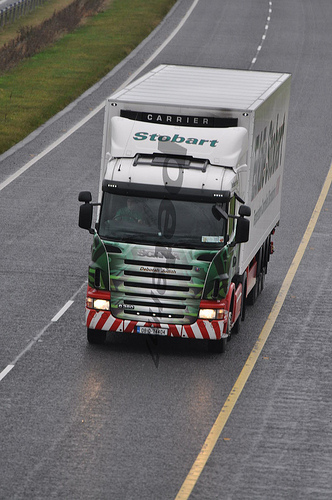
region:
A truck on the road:
[35, 52, 310, 449]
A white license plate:
[131, 317, 171, 339]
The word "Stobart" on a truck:
[129, 126, 222, 153]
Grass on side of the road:
[0, 12, 166, 170]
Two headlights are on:
[90, 293, 219, 325]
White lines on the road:
[1, 2, 275, 382]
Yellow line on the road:
[171, 160, 329, 498]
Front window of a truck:
[95, 184, 232, 249]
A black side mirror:
[72, 187, 102, 238]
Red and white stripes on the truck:
[83, 301, 229, 343]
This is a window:
[115, 188, 300, 302]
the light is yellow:
[77, 296, 248, 317]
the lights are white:
[87, 283, 294, 309]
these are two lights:
[89, 284, 271, 348]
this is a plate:
[107, 316, 171, 356]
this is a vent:
[138, 242, 172, 320]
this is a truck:
[94, 255, 256, 356]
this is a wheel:
[214, 292, 250, 368]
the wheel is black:
[192, 292, 266, 392]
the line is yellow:
[183, 442, 227, 488]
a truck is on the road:
[70, 74, 305, 301]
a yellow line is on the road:
[143, 405, 265, 498]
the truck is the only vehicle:
[83, 126, 306, 347]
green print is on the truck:
[121, 119, 281, 187]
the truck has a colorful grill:
[91, 244, 328, 386]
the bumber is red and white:
[86, 284, 303, 359]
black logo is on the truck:
[111, 94, 294, 174]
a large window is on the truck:
[90, 175, 288, 287]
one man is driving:
[112, 184, 179, 272]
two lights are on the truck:
[74, 282, 255, 344]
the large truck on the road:
[77, 63, 291, 351]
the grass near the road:
[0, 0, 178, 155]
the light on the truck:
[93, 299, 109, 310]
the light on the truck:
[198, 309, 215, 319]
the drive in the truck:
[114, 198, 144, 224]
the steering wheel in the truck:
[112, 213, 138, 222]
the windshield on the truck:
[97, 191, 226, 245]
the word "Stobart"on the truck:
[133, 131, 218, 147]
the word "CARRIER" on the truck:
[147, 113, 207, 124]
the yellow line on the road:
[175, 160, 330, 499]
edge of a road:
[237, 428, 255, 458]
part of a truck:
[203, 330, 207, 338]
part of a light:
[210, 329, 211, 364]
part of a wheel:
[220, 352, 223, 358]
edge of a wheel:
[167, 320, 169, 337]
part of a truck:
[198, 342, 199, 345]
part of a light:
[102, 296, 111, 311]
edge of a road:
[254, 417, 267, 434]